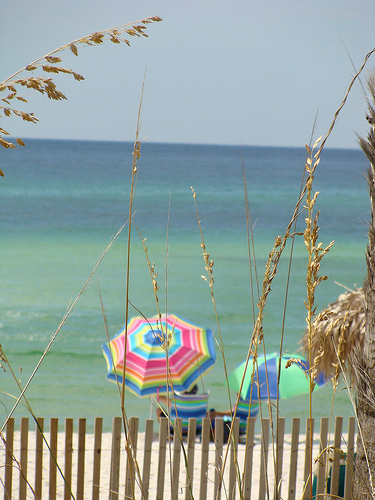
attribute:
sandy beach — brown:
[7, 416, 344, 495]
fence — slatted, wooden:
[0, 414, 359, 498]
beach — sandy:
[0, 425, 363, 497]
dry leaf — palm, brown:
[305, 279, 373, 415]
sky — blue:
[184, 32, 303, 81]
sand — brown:
[100, 449, 109, 494]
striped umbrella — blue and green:
[221, 351, 332, 400]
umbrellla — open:
[99, 311, 225, 406]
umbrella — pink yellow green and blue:
[94, 308, 222, 400]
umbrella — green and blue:
[220, 349, 333, 404]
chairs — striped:
[156, 382, 304, 452]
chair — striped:
[173, 383, 212, 432]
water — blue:
[3, 138, 374, 240]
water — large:
[0, 135, 374, 431]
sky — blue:
[0, 0, 372, 150]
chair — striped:
[159, 387, 213, 440]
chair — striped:
[214, 390, 267, 443]